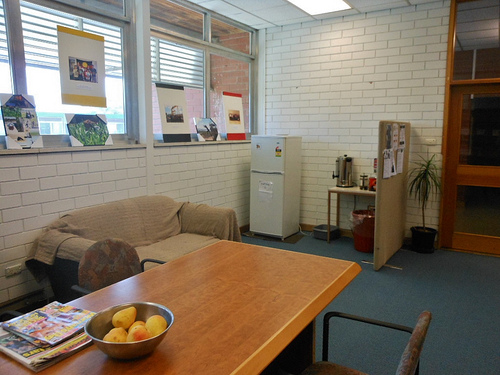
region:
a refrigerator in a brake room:
[239, 127, 307, 235]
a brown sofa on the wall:
[25, 185, 240, 295]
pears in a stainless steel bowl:
[77, 295, 178, 360]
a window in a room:
[9, 0, 147, 143]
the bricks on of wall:
[280, 40, 391, 95]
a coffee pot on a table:
[325, 150, 357, 195]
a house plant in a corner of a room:
[402, 143, 440, 258]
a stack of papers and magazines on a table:
[0, 297, 107, 368]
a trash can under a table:
[347, 201, 387, 254]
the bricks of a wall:
[174, 155, 234, 195]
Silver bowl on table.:
[86, 299, 175, 357]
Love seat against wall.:
[36, 190, 240, 285]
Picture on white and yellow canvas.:
[54, 22, 109, 114]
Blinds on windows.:
[0, 8, 211, 93]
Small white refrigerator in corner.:
[247, 130, 300, 239]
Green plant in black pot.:
[409, 150, 438, 255]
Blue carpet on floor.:
[352, 255, 464, 373]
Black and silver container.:
[331, 153, 351, 191]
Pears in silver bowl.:
[75, 298, 175, 363]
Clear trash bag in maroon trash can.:
[349, 207, 374, 258]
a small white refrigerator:
[248, 134, 303, 237]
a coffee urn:
[334, 153, 355, 189]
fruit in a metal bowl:
[91, 309, 170, 353]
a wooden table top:
[194, 261, 298, 324]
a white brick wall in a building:
[290, 38, 420, 105]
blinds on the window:
[160, 46, 204, 82]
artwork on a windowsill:
[2, 90, 44, 158]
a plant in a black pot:
[406, 150, 440, 254]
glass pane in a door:
[460, 92, 499, 164]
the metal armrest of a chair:
[327, 308, 413, 345]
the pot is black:
[412, 222, 435, 257]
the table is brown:
[208, 262, 271, 320]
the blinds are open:
[152, 41, 207, 86]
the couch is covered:
[49, 192, 227, 239]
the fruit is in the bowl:
[79, 302, 181, 357]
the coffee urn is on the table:
[327, 147, 355, 190]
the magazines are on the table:
[0, 298, 86, 373]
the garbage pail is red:
[349, 205, 373, 254]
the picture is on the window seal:
[49, 105, 115, 147]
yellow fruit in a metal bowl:
[100, 303, 168, 371]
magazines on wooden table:
[1, 315, 88, 373]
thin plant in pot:
[411, 153, 446, 265]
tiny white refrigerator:
[244, 120, 310, 256]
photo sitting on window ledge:
[63, 110, 148, 157]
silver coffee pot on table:
[329, 142, 354, 195]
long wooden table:
[183, 243, 325, 324]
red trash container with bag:
[348, 196, 385, 261]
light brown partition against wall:
[366, 104, 426, 288]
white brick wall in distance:
[300, 40, 407, 128]